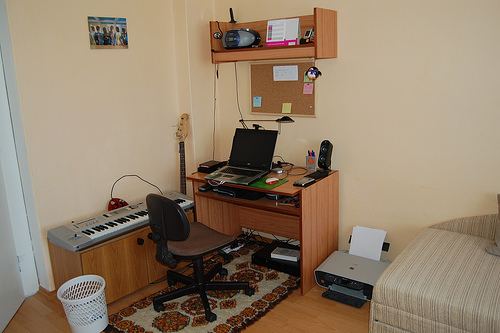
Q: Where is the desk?
A: In the corner.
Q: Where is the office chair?
A: Near the desk.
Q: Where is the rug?
A: Under the chair.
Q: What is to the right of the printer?
A: A couch.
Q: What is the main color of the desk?
A: Brown.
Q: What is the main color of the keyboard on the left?
A: Silver.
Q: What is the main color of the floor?
A: Brown.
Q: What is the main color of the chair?
A: Black.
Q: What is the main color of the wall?
A: White.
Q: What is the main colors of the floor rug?
A: Orange white and black.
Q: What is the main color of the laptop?
A: Silver.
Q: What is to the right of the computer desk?
A: A printer.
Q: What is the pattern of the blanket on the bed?
A: Stripes.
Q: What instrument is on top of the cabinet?
A: A keyboard.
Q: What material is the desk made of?
A: Wood.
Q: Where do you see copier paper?
A: The printer.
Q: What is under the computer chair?
A: A rug.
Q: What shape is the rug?
A: Rectangle.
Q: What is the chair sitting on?
A: Rug.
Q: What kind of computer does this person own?
A: Laptop.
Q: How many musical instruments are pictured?
A: 2.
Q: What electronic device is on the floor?
A: Printer.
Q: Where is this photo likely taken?
A: Dorm room.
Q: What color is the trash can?
A: White.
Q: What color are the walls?
A: Beige.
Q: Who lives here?
A: Musician.